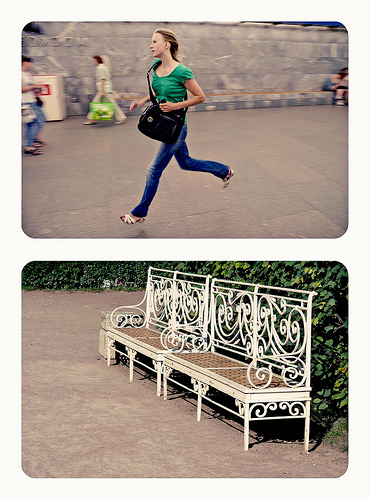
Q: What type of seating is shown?
A: Bench.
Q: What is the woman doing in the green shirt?
A: Running.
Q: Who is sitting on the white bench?
A: Nobody.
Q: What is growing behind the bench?
A: Ivy.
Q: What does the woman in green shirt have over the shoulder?
A: Bag.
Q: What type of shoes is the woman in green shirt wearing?
A: Sandals.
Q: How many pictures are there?
A: 2.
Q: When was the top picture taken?
A: Daytime.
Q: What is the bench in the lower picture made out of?
A: Metal.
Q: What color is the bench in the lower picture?
A: White.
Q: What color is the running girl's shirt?
A: Green.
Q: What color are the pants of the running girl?
A: Blue.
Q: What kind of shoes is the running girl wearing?
A: Open toed.